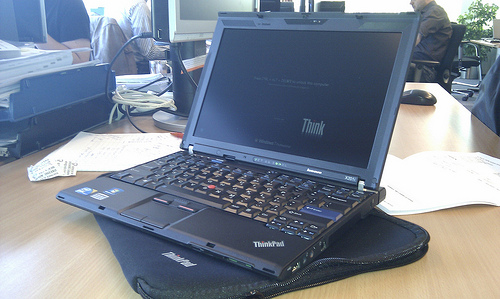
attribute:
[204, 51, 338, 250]
laptop — black, thinkpad, booting, alone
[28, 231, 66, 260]
table — oak, wood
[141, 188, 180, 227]
trackpad — here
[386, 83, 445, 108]
mouse — black, here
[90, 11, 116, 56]
person — sitting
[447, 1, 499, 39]
tree — background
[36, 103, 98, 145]
bag — black